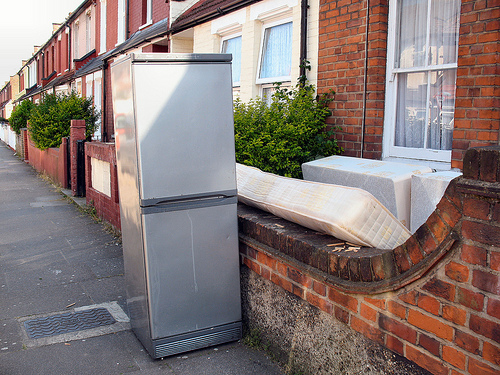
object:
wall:
[76, 141, 479, 365]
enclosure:
[18, 112, 68, 194]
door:
[138, 200, 241, 341]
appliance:
[111, 53, 243, 359]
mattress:
[235, 158, 410, 259]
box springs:
[237, 141, 411, 238]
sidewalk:
[0, 143, 144, 346]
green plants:
[234, 58, 332, 178]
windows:
[378, 1, 450, 156]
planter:
[27, 94, 103, 150]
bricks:
[462, 71, 493, 103]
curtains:
[400, 6, 452, 66]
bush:
[6, 98, 36, 134]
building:
[0, 1, 499, 374]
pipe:
[360, 1, 370, 156]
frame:
[381, 0, 402, 143]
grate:
[90, 153, 111, 200]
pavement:
[1, 141, 127, 309]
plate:
[83, 155, 118, 197]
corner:
[128, 52, 191, 109]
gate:
[71, 133, 90, 194]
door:
[132, 59, 243, 192]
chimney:
[51, 23, 65, 33]